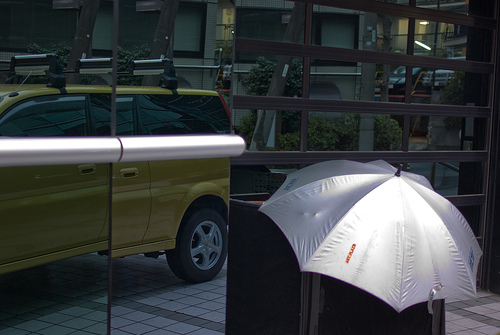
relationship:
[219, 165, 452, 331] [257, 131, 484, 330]
bin under umbrella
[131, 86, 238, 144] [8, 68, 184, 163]
light reflected on window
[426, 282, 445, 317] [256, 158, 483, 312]
strap on umbrella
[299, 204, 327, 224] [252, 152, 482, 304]
bump poking through umbrella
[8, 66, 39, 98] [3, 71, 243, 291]
antenna on front of vehicle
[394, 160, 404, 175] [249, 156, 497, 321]
cap on umbrella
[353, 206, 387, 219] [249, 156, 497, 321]
white on umbrella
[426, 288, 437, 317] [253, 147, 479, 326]
strap on side of umbrella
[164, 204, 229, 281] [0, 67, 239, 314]
tire on side of vehicle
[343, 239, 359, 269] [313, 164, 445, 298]
label on unbrella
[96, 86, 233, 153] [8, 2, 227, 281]
window on vehicle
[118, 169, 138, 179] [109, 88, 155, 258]
handle on door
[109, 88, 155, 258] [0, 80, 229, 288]
door of vehicle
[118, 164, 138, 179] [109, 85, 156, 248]
handle on car door